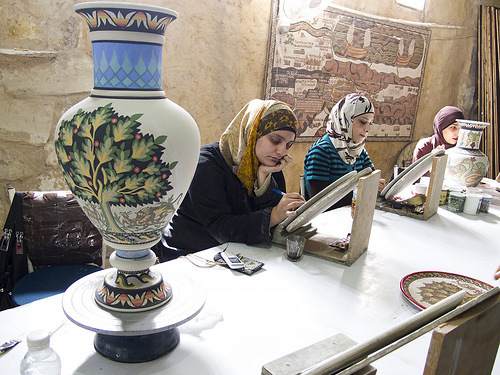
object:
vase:
[52, 0, 202, 252]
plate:
[397, 270, 495, 317]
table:
[0, 174, 499, 374]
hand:
[265, 190, 304, 220]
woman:
[150, 96, 305, 263]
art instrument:
[270, 189, 287, 197]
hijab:
[216, 96, 295, 197]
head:
[248, 101, 302, 168]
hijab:
[322, 90, 374, 167]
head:
[333, 90, 378, 146]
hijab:
[430, 104, 466, 154]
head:
[431, 103, 468, 147]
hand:
[255, 152, 290, 177]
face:
[253, 125, 295, 169]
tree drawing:
[52, 99, 181, 237]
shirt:
[300, 130, 377, 211]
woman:
[301, 92, 385, 213]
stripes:
[301, 173, 330, 178]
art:
[258, 0, 432, 146]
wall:
[0, 1, 500, 242]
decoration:
[256, 0, 433, 144]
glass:
[283, 232, 305, 263]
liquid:
[289, 252, 301, 260]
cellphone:
[217, 249, 247, 273]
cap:
[26, 328, 54, 348]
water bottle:
[18, 330, 61, 374]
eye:
[267, 133, 283, 147]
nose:
[271, 142, 288, 158]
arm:
[188, 165, 274, 247]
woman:
[411, 105, 468, 175]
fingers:
[282, 207, 297, 217]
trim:
[398, 265, 495, 316]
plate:
[277, 169, 360, 229]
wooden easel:
[267, 167, 384, 268]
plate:
[381, 146, 448, 200]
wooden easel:
[374, 150, 449, 222]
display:
[60, 250, 211, 364]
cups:
[459, 194, 482, 217]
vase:
[441, 117, 489, 190]